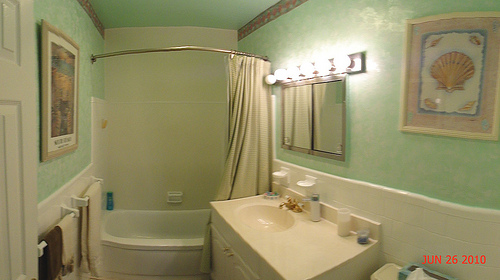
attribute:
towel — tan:
[80, 185, 105, 269]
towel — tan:
[59, 214, 81, 269]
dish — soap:
[163, 186, 185, 201]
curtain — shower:
[199, 50, 280, 275]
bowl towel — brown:
[41, 225, 64, 278]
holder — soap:
[167, 191, 184, 203]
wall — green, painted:
[357, 122, 384, 155]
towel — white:
[78, 165, 118, 276]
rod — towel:
[69, 175, 103, 207]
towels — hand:
[49, 190, 119, 278]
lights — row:
[253, 42, 366, 87]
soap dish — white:
[163, 187, 186, 208]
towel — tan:
[81, 180, 104, 279]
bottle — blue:
[105, 191, 114, 210]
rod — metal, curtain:
[90, 44, 269, 63]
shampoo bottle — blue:
[104, 191, 114, 211]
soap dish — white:
[297, 174, 320, 189]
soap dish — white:
[267, 165, 288, 187]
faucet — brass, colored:
[276, 193, 296, 212]